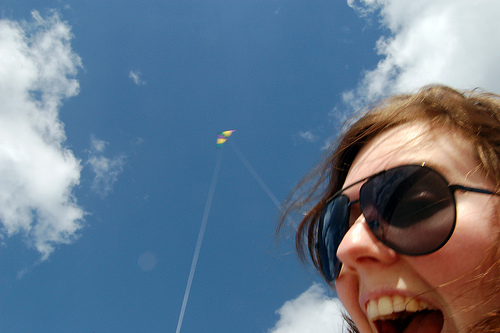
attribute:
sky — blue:
[85, 5, 329, 124]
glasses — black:
[318, 165, 457, 283]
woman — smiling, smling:
[273, 83, 499, 333]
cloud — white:
[0, 2, 85, 266]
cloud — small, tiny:
[128, 69, 146, 87]